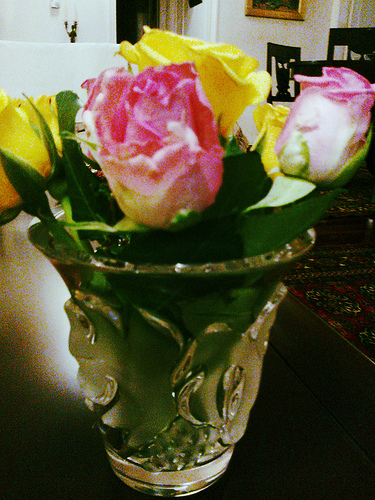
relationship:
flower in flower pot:
[274, 65, 374, 188] [25, 220, 317, 500]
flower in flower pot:
[72, 57, 251, 224] [25, 220, 317, 500]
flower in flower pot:
[1, 73, 75, 212] [25, 220, 317, 500]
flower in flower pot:
[133, 26, 272, 131] [25, 220, 317, 500]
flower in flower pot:
[0, 86, 63, 212] [25, 220, 317, 500]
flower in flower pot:
[72, 60, 225, 228] [25, 220, 317, 500]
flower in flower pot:
[118, 26, 272, 138] [25, 220, 317, 500]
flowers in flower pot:
[249, 102, 289, 178] [25, 220, 317, 500]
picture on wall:
[240, 0, 305, 21] [218, 1, 333, 108]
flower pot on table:
[25, 220, 317, 500] [50, 190, 369, 466]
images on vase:
[63, 280, 289, 453] [26, 238, 303, 497]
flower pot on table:
[25, 220, 317, 500] [9, 209, 373, 498]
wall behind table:
[12, 8, 145, 104] [46, 83, 370, 282]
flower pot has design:
[25, 220, 317, 500] [63, 279, 260, 452]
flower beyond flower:
[118, 26, 272, 138] [72, 60, 225, 228]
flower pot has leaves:
[25, 220, 317, 500] [227, 136, 367, 239]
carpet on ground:
[281, 180, 375, 365] [288, 287, 360, 432]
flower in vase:
[72, 60, 225, 228] [66, 245, 282, 337]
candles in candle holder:
[47, 9, 94, 48] [48, 9, 94, 62]